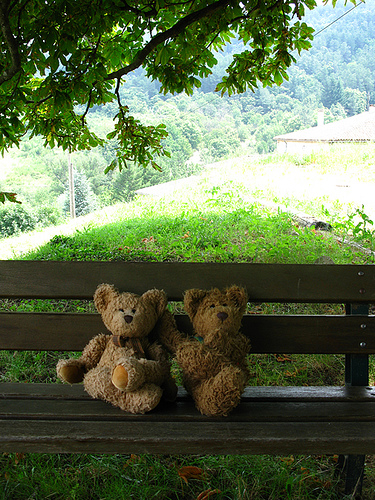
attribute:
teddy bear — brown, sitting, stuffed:
[55, 282, 170, 415]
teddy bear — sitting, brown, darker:
[178, 285, 250, 414]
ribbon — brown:
[116, 335, 144, 357]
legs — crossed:
[182, 347, 241, 419]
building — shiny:
[278, 110, 372, 155]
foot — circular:
[112, 363, 127, 389]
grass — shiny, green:
[30, 146, 373, 266]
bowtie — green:
[192, 336, 205, 344]